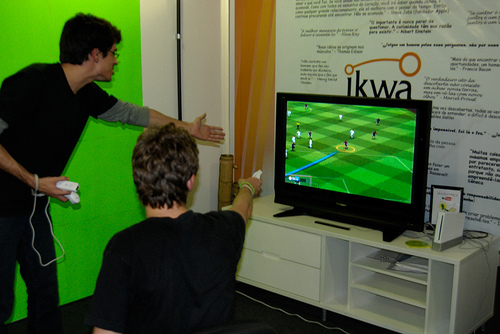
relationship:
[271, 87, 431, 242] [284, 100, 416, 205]
television on screen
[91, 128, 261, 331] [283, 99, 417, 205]
man playing video game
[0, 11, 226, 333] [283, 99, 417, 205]
man playing video game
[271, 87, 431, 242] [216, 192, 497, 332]
television sitting on table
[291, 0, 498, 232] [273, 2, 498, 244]
writing on wall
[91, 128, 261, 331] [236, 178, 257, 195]
man wears bracelet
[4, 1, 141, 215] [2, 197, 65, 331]
man wears pants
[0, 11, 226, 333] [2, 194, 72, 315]
man wears pants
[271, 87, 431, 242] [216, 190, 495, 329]
television on stand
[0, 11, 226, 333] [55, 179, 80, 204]
man holds controller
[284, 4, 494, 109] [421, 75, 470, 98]
words on wall